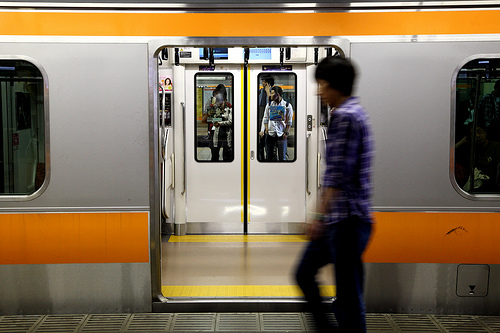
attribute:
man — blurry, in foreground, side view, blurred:
[296, 55, 374, 332]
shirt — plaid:
[313, 104, 372, 224]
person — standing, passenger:
[207, 80, 238, 161]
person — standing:
[262, 79, 293, 158]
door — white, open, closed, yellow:
[182, 66, 306, 222]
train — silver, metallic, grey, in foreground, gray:
[2, 10, 492, 312]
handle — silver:
[177, 98, 190, 194]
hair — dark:
[315, 55, 355, 93]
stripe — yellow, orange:
[1, 11, 500, 34]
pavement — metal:
[8, 303, 497, 333]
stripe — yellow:
[0, 213, 150, 261]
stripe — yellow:
[241, 66, 251, 233]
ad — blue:
[242, 44, 273, 58]